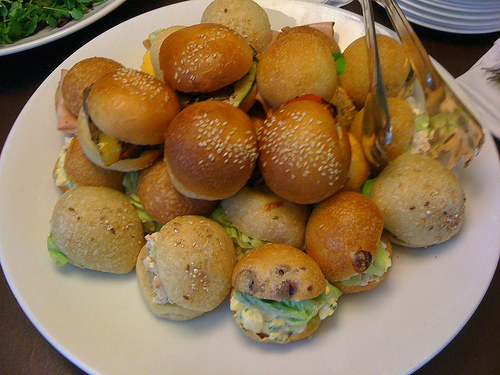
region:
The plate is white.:
[56, 308, 127, 345]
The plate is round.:
[9, 275, 125, 374]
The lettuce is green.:
[4, 0, 98, 57]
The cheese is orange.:
[137, 45, 167, 78]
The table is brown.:
[5, 321, 36, 372]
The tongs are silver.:
[357, 0, 485, 176]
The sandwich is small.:
[228, 240, 328, 348]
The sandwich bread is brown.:
[225, 245, 335, 350]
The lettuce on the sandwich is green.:
[231, 242, 341, 347]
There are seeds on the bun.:
[166, 101, 258, 196]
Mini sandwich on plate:
[224, 243, 344, 348]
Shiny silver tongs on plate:
[351, 0, 488, 177]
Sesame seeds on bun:
[185, 107, 260, 171]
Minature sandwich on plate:
[69, 76, 174, 176]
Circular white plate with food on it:
[3, 0, 496, 374]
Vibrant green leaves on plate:
[1, 0, 96, 42]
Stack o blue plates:
[378, 1, 498, 41]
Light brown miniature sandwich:
[135, 220, 231, 325]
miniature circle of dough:
[45, 190, 142, 272]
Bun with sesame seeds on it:
[160, 16, 251, 91]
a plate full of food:
[5, 12, 497, 374]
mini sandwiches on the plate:
[60, 47, 454, 359]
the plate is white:
[19, 111, 43, 177]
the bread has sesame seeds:
[196, 121, 278, 173]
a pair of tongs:
[343, 6, 492, 162]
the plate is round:
[20, 68, 52, 226]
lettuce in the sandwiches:
[126, 181, 161, 226]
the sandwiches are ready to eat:
[81, 40, 394, 315]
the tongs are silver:
[365, 27, 482, 164]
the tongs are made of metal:
[365, 74, 482, 166]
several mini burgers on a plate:
[12, 1, 492, 374]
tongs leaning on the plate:
[349, 1, 481, 175]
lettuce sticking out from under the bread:
[235, 290, 351, 336]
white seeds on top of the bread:
[180, 105, 256, 187]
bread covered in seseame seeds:
[259, 107, 351, 201]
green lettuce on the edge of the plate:
[2, 1, 101, 49]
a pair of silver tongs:
[353, 2, 483, 174]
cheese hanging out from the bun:
[94, 128, 124, 164]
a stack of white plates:
[382, 1, 499, 39]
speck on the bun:
[109, 226, 118, 236]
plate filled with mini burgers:
[4, 0, 499, 374]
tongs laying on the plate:
[353, 0, 482, 165]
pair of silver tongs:
[354, 0, 485, 173]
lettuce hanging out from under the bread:
[229, 288, 354, 338]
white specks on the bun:
[169, 106, 257, 188]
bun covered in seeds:
[257, 107, 352, 199]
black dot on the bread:
[65, 202, 81, 215]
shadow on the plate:
[239, 331, 333, 353]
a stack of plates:
[378, 0, 497, 37]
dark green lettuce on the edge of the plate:
[0, 1, 127, 56]